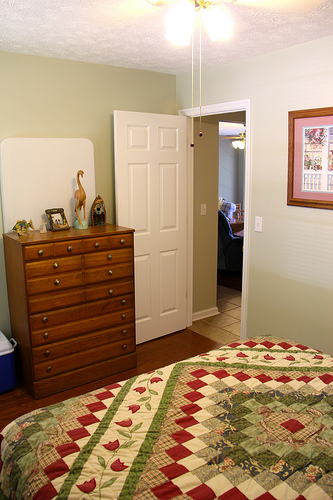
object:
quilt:
[0, 334, 332, 500]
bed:
[0, 334, 332, 500]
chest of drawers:
[2, 222, 137, 401]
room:
[0, 0, 333, 500]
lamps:
[163, 4, 194, 52]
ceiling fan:
[161, 0, 237, 149]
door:
[112, 110, 188, 346]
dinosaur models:
[72, 171, 86, 228]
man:
[216, 201, 244, 244]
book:
[232, 220, 244, 238]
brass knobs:
[36, 248, 44, 257]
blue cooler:
[0, 331, 19, 393]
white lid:
[0, 329, 18, 356]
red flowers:
[101, 437, 121, 452]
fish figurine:
[89, 194, 106, 229]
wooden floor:
[0, 326, 226, 433]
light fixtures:
[193, 0, 216, 8]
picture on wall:
[292, 113, 333, 203]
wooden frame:
[287, 107, 333, 119]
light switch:
[253, 216, 262, 234]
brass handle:
[42, 314, 48, 325]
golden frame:
[2, 231, 36, 403]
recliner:
[217, 214, 244, 282]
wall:
[174, 34, 333, 359]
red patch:
[174, 413, 200, 430]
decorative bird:
[12, 219, 35, 237]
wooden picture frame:
[286, 105, 333, 211]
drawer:
[26, 245, 134, 280]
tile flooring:
[186, 317, 242, 346]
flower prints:
[113, 415, 144, 442]